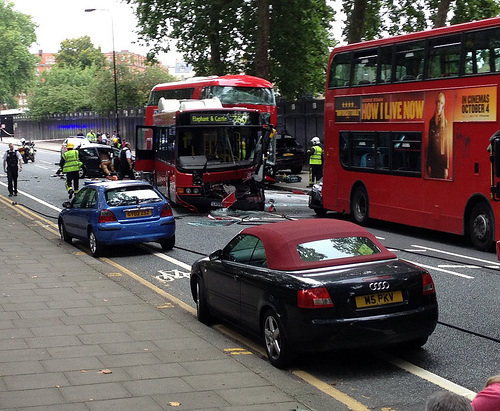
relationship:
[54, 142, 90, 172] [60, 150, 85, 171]
man in vest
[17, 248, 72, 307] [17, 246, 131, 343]
gray blocks sidewalk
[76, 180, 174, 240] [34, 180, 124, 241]
blue car parked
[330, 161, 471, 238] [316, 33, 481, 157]
red double bus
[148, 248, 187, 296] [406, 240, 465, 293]
whit bike street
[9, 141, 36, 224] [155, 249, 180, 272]
policeman wearing white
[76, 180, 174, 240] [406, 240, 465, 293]
car accident street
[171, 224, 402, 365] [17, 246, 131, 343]
car on sidewalk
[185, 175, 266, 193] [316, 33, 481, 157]
damage front bus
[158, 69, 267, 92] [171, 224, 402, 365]
roof of car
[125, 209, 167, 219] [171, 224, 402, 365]
plat on car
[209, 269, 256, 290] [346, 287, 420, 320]
black lettering plate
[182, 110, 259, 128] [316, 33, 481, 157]
banner top bus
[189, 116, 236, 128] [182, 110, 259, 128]
lettering on banner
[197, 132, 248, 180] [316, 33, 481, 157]
woman on bus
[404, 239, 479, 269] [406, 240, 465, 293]
lines on street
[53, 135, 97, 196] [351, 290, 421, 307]
worker in yellow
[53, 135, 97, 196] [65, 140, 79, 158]
worker in helmet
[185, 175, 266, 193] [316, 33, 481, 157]
damage red bus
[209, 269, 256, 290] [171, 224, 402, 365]
black car sedan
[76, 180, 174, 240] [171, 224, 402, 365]
blue hatchback car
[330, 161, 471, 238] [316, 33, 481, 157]
red decker bus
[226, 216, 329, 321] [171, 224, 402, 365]
hatchback black car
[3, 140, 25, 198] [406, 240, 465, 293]
policeman man street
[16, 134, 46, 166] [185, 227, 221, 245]
motorcycle on road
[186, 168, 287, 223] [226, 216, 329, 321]
wrecked black hatchback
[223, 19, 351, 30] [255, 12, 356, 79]
full tall trees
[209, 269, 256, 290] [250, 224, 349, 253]
black car top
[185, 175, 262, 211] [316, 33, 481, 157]
damage front bus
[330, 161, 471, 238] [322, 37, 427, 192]
red bus double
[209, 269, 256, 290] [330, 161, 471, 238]
black convertible red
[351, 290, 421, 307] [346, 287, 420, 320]
yellow black plate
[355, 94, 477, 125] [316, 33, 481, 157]
ad side bus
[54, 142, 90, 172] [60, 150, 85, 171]
man green vest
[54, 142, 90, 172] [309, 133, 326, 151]
man in hat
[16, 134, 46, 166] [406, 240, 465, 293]
motorcycle on street